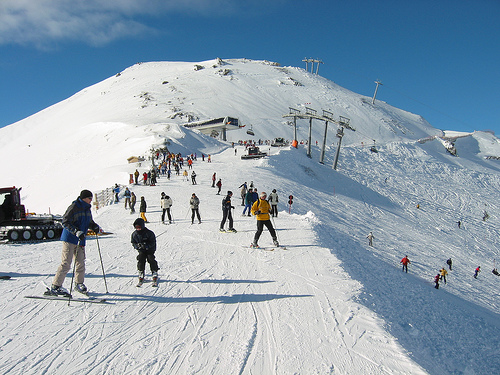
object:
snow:
[42, 101, 278, 331]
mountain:
[0, 54, 499, 374]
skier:
[24, 189, 110, 306]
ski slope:
[0, 65, 500, 374]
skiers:
[122, 150, 281, 250]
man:
[50, 189, 103, 294]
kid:
[130, 218, 159, 288]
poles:
[282, 107, 356, 170]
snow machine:
[241, 144, 267, 160]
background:
[0, 2, 500, 262]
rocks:
[194, 60, 305, 86]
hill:
[441, 130, 498, 154]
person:
[253, 191, 279, 246]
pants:
[253, 220, 277, 244]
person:
[43, 189, 104, 297]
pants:
[52, 240, 86, 286]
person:
[160, 192, 173, 226]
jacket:
[161, 195, 173, 208]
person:
[400, 255, 411, 273]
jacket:
[400, 258, 411, 265]